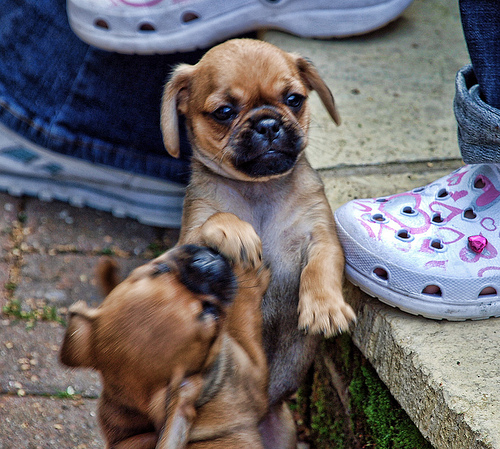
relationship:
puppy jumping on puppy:
[61, 243, 271, 448] [159, 38, 358, 449]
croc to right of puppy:
[334, 164, 499, 321] [159, 38, 358, 449]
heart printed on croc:
[378, 192, 431, 233] [334, 164, 499, 321]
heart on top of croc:
[468, 234, 487, 252] [334, 164, 499, 321]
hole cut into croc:
[421, 284, 441, 296] [334, 164, 499, 321]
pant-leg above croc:
[453, 1, 499, 166] [334, 164, 499, 321]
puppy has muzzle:
[159, 38, 358, 449] [234, 121, 298, 176]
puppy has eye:
[159, 38, 358, 449] [286, 94, 303, 108]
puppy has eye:
[159, 38, 358, 449] [213, 106, 233, 118]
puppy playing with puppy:
[61, 243, 271, 448] [159, 38, 358, 449]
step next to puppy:
[260, 3, 499, 448] [61, 243, 271, 448]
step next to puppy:
[260, 3, 499, 448] [159, 38, 358, 449]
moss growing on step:
[335, 337, 430, 448] [260, 3, 499, 448]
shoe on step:
[67, 1, 416, 55] [260, 3, 499, 448]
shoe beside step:
[1, 124, 185, 229] [260, 3, 499, 448]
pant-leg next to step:
[0, 1, 207, 183] [260, 3, 499, 448]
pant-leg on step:
[453, 1, 499, 166] [260, 3, 499, 448]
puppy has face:
[61, 243, 271, 448] [143, 245, 238, 323]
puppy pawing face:
[159, 38, 358, 449] [143, 245, 238, 323]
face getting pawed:
[143, 245, 238, 323] [201, 212, 263, 267]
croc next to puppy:
[334, 164, 499, 321] [61, 243, 271, 448]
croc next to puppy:
[334, 164, 499, 321] [159, 38, 358, 449]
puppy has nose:
[159, 38, 358, 449] [258, 119, 278, 136]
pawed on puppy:
[201, 212, 263, 267] [61, 243, 271, 448]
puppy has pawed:
[159, 38, 358, 449] [201, 212, 263, 267]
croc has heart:
[334, 164, 499, 321] [378, 192, 431, 233]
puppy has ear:
[159, 38, 358, 449] [159, 63, 191, 157]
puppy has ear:
[159, 38, 358, 449] [295, 53, 341, 126]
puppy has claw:
[61, 243, 271, 448] [233, 259, 271, 298]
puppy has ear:
[61, 243, 271, 448] [59, 300, 103, 369]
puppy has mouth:
[61, 243, 271, 448] [235, 146, 297, 165]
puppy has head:
[61, 243, 271, 448] [62, 245, 234, 449]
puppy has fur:
[61, 243, 271, 448] [59, 258, 272, 449]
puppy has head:
[159, 38, 358, 449] [160, 36, 342, 181]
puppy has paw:
[159, 38, 358, 449] [296, 279, 358, 339]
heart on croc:
[378, 192, 431, 233] [334, 164, 499, 321]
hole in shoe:
[182, 11, 197, 23] [67, 1, 416, 55]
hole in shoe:
[139, 22, 155, 31] [67, 1, 416, 55]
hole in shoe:
[95, 17, 107, 29] [67, 1, 416, 55]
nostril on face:
[260, 126, 267, 136] [204, 81, 309, 168]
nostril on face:
[272, 124, 279, 134] [204, 81, 309, 168]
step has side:
[260, 3, 499, 448] [289, 332, 437, 449]